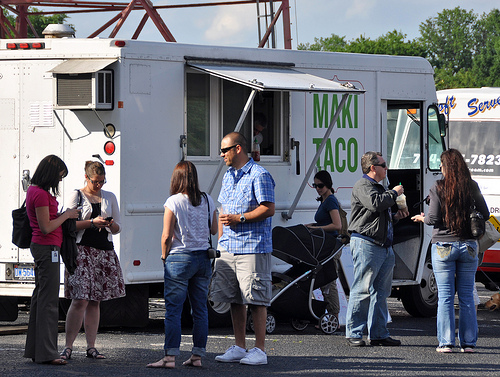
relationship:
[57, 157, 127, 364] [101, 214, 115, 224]
person looking at cell phone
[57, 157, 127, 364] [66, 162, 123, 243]
person wearing cardigan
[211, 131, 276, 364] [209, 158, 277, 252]
guy in shirt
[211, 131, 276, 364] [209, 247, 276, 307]
guy in shorts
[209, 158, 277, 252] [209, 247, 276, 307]
shirt and shorts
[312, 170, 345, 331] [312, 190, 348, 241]
woman wears t-shirt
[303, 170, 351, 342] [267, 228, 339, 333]
woman near baby stroller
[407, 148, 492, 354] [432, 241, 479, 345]
person wears jeans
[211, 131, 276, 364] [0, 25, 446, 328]
guy front truck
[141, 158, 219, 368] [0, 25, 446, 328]
person front truck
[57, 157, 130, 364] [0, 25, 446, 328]
person front truck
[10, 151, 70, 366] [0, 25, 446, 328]
person front truck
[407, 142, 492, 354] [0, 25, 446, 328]
person front truck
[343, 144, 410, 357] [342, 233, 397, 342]
guy wears jacket